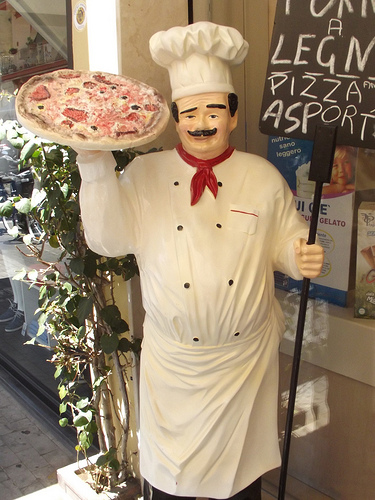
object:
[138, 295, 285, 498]
apron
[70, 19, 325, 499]
body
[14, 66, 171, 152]
pizza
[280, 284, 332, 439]
reflection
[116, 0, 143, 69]
wall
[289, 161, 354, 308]
picture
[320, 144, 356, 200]
baby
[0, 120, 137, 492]
plant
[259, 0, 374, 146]
writing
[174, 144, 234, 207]
scarf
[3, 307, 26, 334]
shoes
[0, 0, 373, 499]
outside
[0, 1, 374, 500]
daytime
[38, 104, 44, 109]
olives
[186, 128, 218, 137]
mustache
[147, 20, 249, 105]
chef hat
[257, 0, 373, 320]
sign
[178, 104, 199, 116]
eyebrow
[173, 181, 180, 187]
buttons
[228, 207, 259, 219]
pocket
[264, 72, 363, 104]
pizza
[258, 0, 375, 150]
chalkboard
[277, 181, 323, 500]
stick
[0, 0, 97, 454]
window